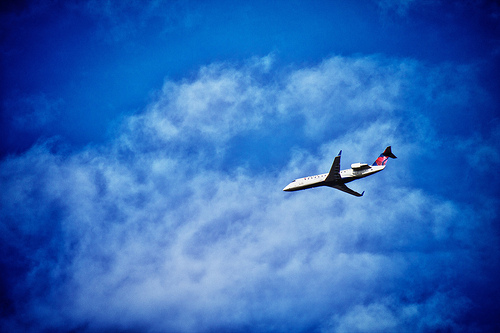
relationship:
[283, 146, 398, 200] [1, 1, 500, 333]
airplane in sky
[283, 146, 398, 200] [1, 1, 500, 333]
airplane flies through sky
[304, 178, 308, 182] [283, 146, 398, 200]
window on plane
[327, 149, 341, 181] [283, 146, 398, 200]
wing of airplane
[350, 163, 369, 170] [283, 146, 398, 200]
engine on airplane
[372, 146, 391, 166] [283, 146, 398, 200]
tail of airplane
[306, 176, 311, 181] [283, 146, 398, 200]
window on airplane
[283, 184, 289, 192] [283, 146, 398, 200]
nose of airplane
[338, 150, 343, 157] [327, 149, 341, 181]
tip of wing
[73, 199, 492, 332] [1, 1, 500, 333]
clouds in sky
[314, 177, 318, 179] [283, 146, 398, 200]
window on airplane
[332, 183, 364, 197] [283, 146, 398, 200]
wing on airplane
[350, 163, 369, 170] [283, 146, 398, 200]
engine on side of airplane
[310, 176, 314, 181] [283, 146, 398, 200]
window on airplane